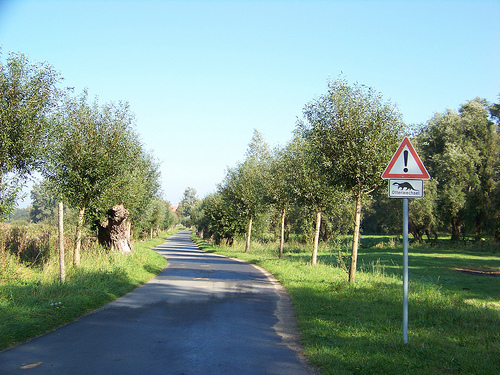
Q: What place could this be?
A: It is a road.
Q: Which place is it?
A: It is a road.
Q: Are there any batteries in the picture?
A: No, there are no batteries.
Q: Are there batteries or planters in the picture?
A: No, there are no batteries or planters.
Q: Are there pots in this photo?
A: No, there are no pots.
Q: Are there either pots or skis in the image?
A: No, there are no pots or skis.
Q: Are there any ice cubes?
A: No, there are no ice cubes.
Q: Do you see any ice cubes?
A: No, there are no ice cubes.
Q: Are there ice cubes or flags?
A: No, there are no ice cubes or flags.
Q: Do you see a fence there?
A: No, there are no fences.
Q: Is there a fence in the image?
A: No, there are no fences.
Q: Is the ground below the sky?
A: Yes, the ground is below the sky.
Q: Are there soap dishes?
A: No, there are no soap dishes.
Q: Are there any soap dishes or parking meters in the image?
A: No, there are no soap dishes or parking meters.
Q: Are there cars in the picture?
A: No, there are no cars.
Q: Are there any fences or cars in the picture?
A: No, there are no cars or fences.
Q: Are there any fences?
A: No, there are no fences.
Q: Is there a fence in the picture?
A: No, there are no fences.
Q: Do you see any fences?
A: No, there are no fences.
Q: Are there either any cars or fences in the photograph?
A: No, there are no fences or cars.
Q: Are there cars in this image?
A: No, there are no cars.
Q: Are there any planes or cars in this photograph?
A: No, there are no cars or planes.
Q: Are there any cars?
A: No, there are no cars.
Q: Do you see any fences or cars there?
A: No, there are no cars or fences.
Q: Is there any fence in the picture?
A: No, there are no fences.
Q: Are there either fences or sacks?
A: No, there are no fences or sacks.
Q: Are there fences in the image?
A: No, there are no fences.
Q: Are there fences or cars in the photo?
A: No, there are no fences or cars.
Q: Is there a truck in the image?
A: No, there are no trucks.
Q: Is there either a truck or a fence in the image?
A: No, there are no trucks or fences.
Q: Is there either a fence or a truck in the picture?
A: No, there are no trucks or fences.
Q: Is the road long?
A: Yes, the road is long.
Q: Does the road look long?
A: Yes, the road is long.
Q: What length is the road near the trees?
A: The road is long.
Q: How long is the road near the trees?
A: The road is long.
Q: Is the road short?
A: No, the road is long.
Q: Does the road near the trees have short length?
A: No, the road is long.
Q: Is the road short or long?
A: The road is long.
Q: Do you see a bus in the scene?
A: No, there are no buses.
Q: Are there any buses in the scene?
A: No, there are no buses.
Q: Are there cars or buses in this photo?
A: No, there are no buses or cars.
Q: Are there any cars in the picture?
A: No, there are no cars.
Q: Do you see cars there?
A: No, there are no cars.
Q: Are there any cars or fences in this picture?
A: No, there are no cars or fences.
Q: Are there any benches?
A: No, there are no benches.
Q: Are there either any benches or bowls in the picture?
A: No, there are no benches or bowls.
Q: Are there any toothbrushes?
A: No, there are no toothbrushes.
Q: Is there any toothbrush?
A: No, there are no toothbrushes.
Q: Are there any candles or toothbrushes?
A: No, there are no toothbrushes or candles.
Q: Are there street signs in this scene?
A: Yes, there is a street sign.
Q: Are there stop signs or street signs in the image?
A: Yes, there is a street sign.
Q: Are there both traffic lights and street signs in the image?
A: No, there is a street sign but no traffic lights.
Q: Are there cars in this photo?
A: No, there are no cars.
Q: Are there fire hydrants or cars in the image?
A: No, there are no cars or fire hydrants.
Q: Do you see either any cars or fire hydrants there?
A: No, there are no cars or fire hydrants.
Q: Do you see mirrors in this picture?
A: No, there are no mirrors.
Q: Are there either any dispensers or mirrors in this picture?
A: No, there are no mirrors or dispensers.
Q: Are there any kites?
A: No, there are no kites.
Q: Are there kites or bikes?
A: No, there are no kites or bikes.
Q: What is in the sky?
A: The clouds are in the sky.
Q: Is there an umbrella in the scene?
A: No, there are no umbrellas.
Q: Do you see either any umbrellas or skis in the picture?
A: No, there are no umbrellas or skis.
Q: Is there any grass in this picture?
A: Yes, there is grass.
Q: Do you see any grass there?
A: Yes, there is grass.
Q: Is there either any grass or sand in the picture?
A: Yes, there is grass.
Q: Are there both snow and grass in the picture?
A: No, there is grass but no snow.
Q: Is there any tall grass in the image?
A: Yes, there is tall grass.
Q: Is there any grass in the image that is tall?
A: Yes, there is grass that is tall.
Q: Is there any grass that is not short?
A: Yes, there is tall grass.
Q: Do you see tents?
A: No, there are no tents.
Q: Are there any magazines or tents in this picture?
A: No, there are no tents or magazines.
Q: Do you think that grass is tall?
A: Yes, the grass is tall.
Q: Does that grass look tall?
A: Yes, the grass is tall.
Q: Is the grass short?
A: No, the grass is tall.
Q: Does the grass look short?
A: No, the grass is tall.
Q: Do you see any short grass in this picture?
A: No, there is grass but it is tall.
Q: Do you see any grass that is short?
A: No, there is grass but it is tall.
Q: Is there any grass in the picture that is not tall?
A: No, there is grass but it is tall.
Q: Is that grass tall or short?
A: The grass is tall.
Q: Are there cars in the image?
A: No, there are no cars.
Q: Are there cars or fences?
A: No, there are no cars or fences.